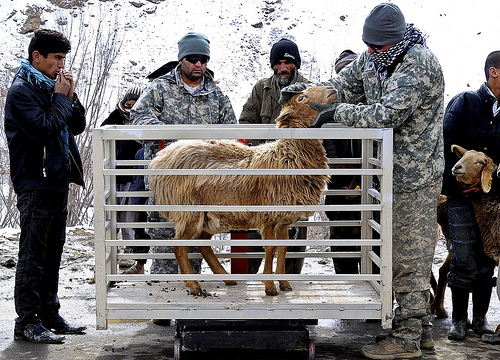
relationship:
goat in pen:
[140, 81, 339, 298] [91, 124, 395, 330]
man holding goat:
[277, 1, 446, 360] [140, 81, 339, 298]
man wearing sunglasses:
[128, 33, 238, 328] [185, 54, 210, 65]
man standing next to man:
[277, 1, 446, 360] [240, 38, 316, 276]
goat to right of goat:
[449, 144, 496, 193] [140, 81, 339, 298]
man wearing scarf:
[277, 1, 446, 360] [365, 20, 431, 79]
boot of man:
[359, 337, 423, 359] [277, 1, 446, 360]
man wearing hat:
[240, 38, 316, 276] [269, 37, 302, 72]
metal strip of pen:
[103, 169, 383, 177] [91, 124, 395, 330]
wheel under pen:
[172, 337, 182, 359] [91, 124, 395, 330]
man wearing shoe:
[277, 1, 446, 360] [374, 334, 436, 351]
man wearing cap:
[277, 1, 446, 360] [360, 3, 407, 48]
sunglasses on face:
[185, 54, 210, 65] [181, 57, 207, 81]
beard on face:
[273, 67, 296, 86] [271, 59, 295, 87]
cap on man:
[177, 33, 211, 61] [128, 33, 238, 328]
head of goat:
[452, 149, 487, 185] [447, 143, 500, 267]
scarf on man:
[9, 60, 72, 169] [4, 28, 89, 343]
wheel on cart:
[172, 337, 182, 359] [173, 319, 320, 359]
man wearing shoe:
[4, 28, 89, 343] [38, 310, 87, 334]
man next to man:
[128, 33, 238, 328] [240, 38, 316, 276]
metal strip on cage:
[104, 204, 382, 211] [96, 123, 394, 330]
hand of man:
[51, 71, 71, 97] [4, 28, 89, 343]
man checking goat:
[277, 1, 446, 360] [140, 79, 344, 298]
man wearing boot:
[443, 50, 499, 343] [449, 282, 473, 340]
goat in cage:
[140, 79, 344, 298] [96, 123, 394, 330]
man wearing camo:
[277, 1, 446, 360] [303, 43, 446, 344]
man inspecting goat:
[277, 1, 446, 360] [140, 79, 344, 298]